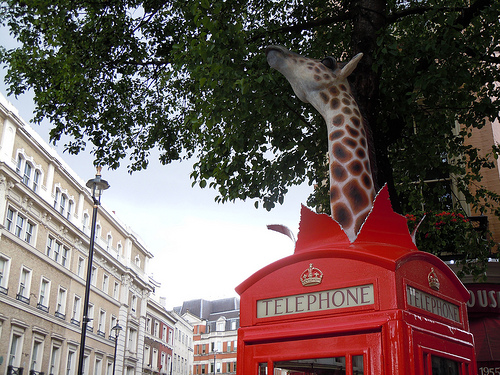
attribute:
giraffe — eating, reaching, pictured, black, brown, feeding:
[261, 37, 396, 245]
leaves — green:
[248, 51, 276, 82]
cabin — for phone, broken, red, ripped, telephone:
[229, 178, 480, 374]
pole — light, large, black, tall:
[70, 163, 110, 375]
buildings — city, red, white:
[169, 293, 252, 375]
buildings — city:
[167, 305, 198, 374]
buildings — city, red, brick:
[136, 291, 178, 375]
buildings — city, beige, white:
[0, 92, 157, 374]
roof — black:
[167, 292, 242, 320]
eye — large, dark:
[317, 55, 339, 76]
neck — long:
[311, 93, 385, 245]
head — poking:
[262, 37, 367, 111]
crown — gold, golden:
[296, 261, 326, 288]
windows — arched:
[14, 148, 46, 194]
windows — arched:
[50, 183, 75, 226]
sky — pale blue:
[1, 1, 451, 311]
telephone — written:
[254, 284, 378, 321]